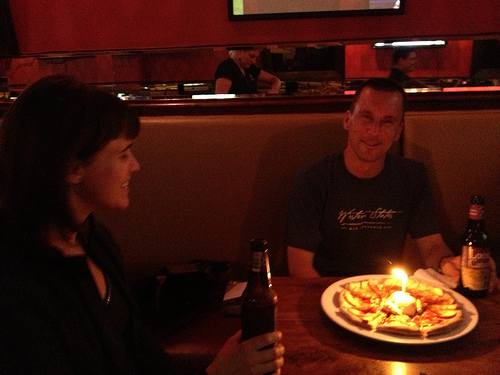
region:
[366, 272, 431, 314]
One candle in the middle of plate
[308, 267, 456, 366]
Plate is white and circular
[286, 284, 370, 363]
Plate is on wood table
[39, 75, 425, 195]
Two people are sitting at table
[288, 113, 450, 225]
Man sitting on booth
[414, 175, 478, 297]
Man holding beer in left hand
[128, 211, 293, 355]
Woman holding beer in right hand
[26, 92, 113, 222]
Woman has dark hair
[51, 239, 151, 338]
Woman wearing black shirt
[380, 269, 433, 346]
Candle is in one scoop of ice cream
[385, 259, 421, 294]
flame on candle in pizza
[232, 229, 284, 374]
beer bottle in woman's hand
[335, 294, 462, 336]
slices of pizza on plate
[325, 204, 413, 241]
logo on man's tee shirt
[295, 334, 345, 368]
wood table in restaurant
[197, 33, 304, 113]
person in restaurant kitchen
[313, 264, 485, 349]
white plate on table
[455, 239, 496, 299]
label on beer bottle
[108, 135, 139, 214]
smiling face on woman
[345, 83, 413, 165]
man looking at camera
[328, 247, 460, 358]
Pizza with candle on it.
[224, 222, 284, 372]
Beer bottle in hand.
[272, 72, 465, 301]
Man getting ready to eat.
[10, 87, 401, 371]
Woman getting ready to eat.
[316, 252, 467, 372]
Food on a white plate.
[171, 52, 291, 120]
Woman behind a bar.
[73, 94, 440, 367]
Two people in a restuarant.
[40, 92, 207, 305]
A woman smiling.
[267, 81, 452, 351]
A man smiling.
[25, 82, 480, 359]
Two people drinking beer.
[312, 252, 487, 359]
A birthday pizza.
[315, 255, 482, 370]
The pizza is cut into slices.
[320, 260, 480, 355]
The pizza is on a white plate.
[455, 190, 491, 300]
A bottle of beer.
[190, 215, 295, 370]
The woman is holding a beer.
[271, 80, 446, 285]
The man is wearing a t-shirt.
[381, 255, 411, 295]
A lit candle.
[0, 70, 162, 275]
The woman is smiling.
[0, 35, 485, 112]
A long horizontal mirror.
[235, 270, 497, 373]
A wooden table.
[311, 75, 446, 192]
a man with very short hair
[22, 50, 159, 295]
a woman with brown hair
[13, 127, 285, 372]
a woman holding a bottle with her hand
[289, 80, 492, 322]
a man holding a bottle in his hand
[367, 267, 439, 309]
a candle on a plate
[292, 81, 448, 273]
a man wearing a black shirt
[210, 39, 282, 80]
a woman with blonde hair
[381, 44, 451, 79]
a man with brown hair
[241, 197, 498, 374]
a wooden table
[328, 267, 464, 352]
food on a white plate